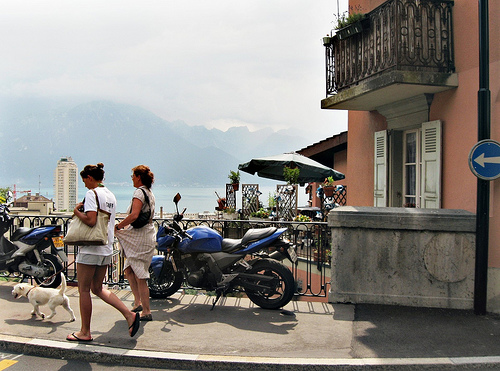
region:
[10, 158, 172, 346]
two ladies walking a dog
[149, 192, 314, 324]
Motorcycle parked on the sidewalk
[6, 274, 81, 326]
Happy dog wagging his tail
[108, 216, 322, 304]
Black rod iron fence along the sidewalk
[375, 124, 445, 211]
Apartment window shutters opened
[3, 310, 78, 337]
Shadow of a dog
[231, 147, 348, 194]
Patio umbrella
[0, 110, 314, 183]
Beautiful clear sky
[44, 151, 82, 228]
one lone skyscraper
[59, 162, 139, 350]
Lady clutching her purse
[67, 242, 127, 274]
these are white shorts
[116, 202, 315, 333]
this is a blue motorcycle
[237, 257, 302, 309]
this is a tire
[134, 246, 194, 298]
this is the front tire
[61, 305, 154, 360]
these are flip flops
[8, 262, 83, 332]
this is a dog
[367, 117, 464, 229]
these are window shutters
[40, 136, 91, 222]
this is a sky scraper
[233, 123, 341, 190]
this is an umbrella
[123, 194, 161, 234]
a small black purse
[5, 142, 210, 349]
Two women walking down the sidewalk.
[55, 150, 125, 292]
The woman is carrying a purse.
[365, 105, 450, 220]
A pair of shutters for the window.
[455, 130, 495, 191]
A street sign.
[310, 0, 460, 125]
A small balcony.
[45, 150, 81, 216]
A high-rise building in the distance.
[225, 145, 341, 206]
A large umbrella.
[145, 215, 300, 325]
A motorcycle parked next to a guardrail.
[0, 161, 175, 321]
The woman is walking the dog.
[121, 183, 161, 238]
The woman is carrying black bag.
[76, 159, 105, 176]
Person has brown hair.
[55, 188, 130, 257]
Tan bag over person's shoulder.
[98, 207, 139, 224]
Person wearing white t-shirt.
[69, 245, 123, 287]
Person wearing shorts.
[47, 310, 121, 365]
Person wearing black flip flops.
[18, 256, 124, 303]
Person walking white dog.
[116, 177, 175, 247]
Black bag around person's shoulder.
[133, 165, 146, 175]
Person has brown hair.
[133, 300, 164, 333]
Person wearing flat shoes.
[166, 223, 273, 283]
Blue and gray bike near fence.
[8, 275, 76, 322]
small white dog walking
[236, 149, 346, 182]
black umbrella over tables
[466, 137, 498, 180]
round blue and white arrow sign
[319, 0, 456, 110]
stone balcony with planter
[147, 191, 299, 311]
parked blue motorcycle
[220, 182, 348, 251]
line of trellises with plants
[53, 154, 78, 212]
tall white building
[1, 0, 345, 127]
gray cloudy sky over mountain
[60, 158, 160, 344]
two women walking down street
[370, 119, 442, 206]
white window shutters